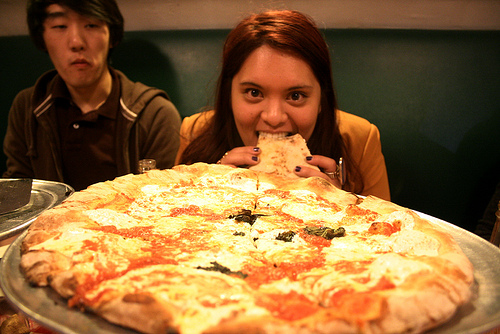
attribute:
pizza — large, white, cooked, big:
[72, 153, 432, 332]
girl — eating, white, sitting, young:
[189, 13, 367, 169]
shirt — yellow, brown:
[191, 113, 375, 176]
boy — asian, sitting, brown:
[15, 5, 178, 160]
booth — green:
[20, 31, 499, 181]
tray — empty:
[0, 173, 70, 226]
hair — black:
[29, 2, 126, 28]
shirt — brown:
[19, 86, 169, 162]